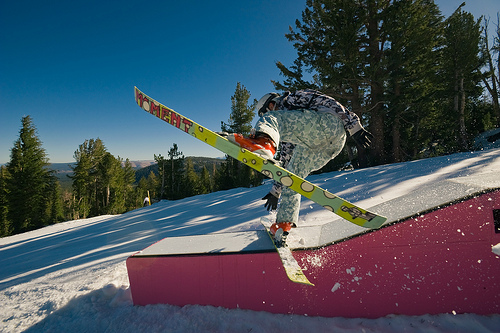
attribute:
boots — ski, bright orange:
[234, 127, 282, 161]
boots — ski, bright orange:
[265, 215, 296, 238]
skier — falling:
[138, 55, 412, 264]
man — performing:
[137, 68, 387, 248]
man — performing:
[167, 79, 422, 264]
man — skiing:
[165, 68, 409, 269]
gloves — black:
[349, 112, 406, 165]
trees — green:
[7, 148, 253, 204]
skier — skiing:
[202, 77, 396, 227]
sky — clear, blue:
[10, 20, 224, 122]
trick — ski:
[125, 85, 492, 316]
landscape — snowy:
[86, 152, 426, 312]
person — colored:
[238, 77, 348, 254]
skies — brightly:
[129, 81, 381, 233]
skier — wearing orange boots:
[203, 84, 373, 250]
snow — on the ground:
[15, 222, 115, 331]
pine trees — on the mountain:
[12, 109, 144, 228]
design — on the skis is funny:
[131, 77, 391, 291]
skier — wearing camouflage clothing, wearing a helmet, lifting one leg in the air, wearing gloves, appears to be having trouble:
[226, 84, 376, 254]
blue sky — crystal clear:
[35, 16, 229, 79]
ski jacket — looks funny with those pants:
[266, 85, 366, 197]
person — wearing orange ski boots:
[223, 89, 379, 255]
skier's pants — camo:
[242, 107, 352, 235]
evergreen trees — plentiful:
[4, 100, 268, 221]